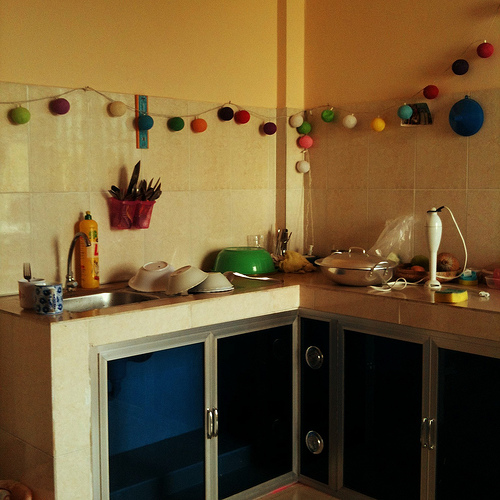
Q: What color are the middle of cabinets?
A: Blue.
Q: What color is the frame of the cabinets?
A: Silver.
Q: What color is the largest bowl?
A: Green.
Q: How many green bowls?
A: One.